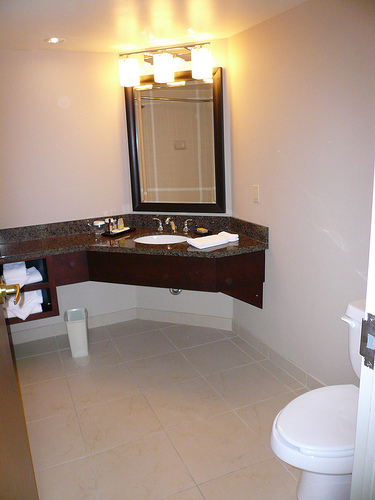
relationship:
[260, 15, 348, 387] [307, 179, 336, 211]
wall has a part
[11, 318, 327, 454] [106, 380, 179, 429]
floor has a part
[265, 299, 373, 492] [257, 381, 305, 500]
toilet has an edge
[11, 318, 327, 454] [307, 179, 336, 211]
floor has a part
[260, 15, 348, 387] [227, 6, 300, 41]
wall has an edge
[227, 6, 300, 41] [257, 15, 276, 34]
edge has a part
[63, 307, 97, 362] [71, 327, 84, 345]
bin has a part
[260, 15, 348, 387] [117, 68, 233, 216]
wall has a mirror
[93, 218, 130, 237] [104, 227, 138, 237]
toiletries on a tray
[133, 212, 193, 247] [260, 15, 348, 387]
sink attached to wall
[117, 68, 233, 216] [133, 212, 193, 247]
mirror above sink